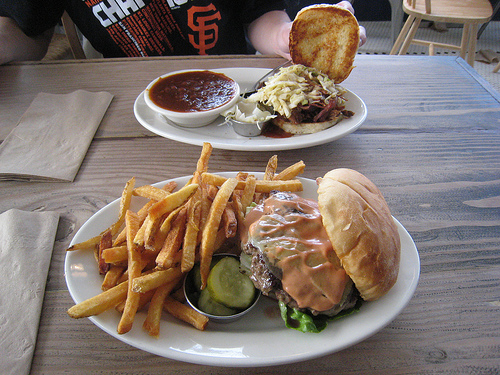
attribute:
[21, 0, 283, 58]
shirt — black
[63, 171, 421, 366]
plate — white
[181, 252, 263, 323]
cup — metal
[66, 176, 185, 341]
fries — of  french,  A side order , golden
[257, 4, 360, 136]
sandwich — pork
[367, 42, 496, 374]
table — wooden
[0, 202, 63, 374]
napkin — paper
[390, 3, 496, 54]
chair — oak, empty, wooden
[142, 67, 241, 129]
bowl — white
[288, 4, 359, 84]
bun — toasted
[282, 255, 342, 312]
dressing —  condiment,  thousand island, colored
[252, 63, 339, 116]
slaw —  topping, of cole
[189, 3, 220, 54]
logo —  San Francisco Giant's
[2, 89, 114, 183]
napkin — brown, folded, paper,  brown,  paper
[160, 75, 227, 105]
sauce — for dipping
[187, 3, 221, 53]
logo —  San Francisco giants